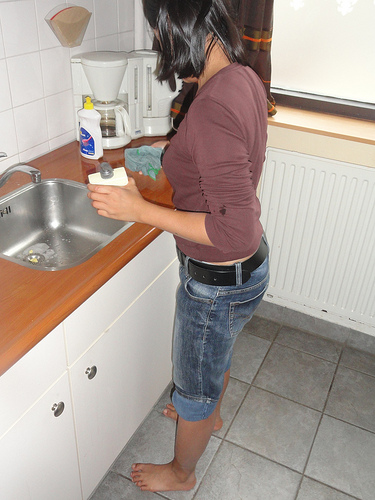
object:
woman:
[86, 0, 273, 493]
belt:
[176, 231, 270, 288]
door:
[68, 256, 181, 500]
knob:
[85, 365, 98, 380]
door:
[0, 366, 84, 500]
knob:
[51, 401, 64, 417]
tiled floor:
[86, 298, 374, 500]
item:
[29, 257, 39, 263]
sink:
[0, 176, 135, 273]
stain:
[219, 204, 227, 216]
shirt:
[159, 60, 270, 264]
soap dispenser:
[87, 161, 129, 190]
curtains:
[230, 0, 278, 118]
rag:
[124, 144, 166, 182]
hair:
[141, 0, 250, 89]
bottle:
[77, 96, 104, 160]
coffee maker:
[80, 48, 132, 151]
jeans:
[169, 233, 270, 423]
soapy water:
[14, 240, 59, 263]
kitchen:
[0, 0, 375, 500]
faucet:
[0, 152, 42, 190]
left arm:
[134, 96, 258, 254]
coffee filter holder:
[42, 4, 92, 49]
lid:
[83, 96, 93, 110]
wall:
[0, 0, 134, 178]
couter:
[0, 136, 176, 377]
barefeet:
[129, 461, 197, 491]